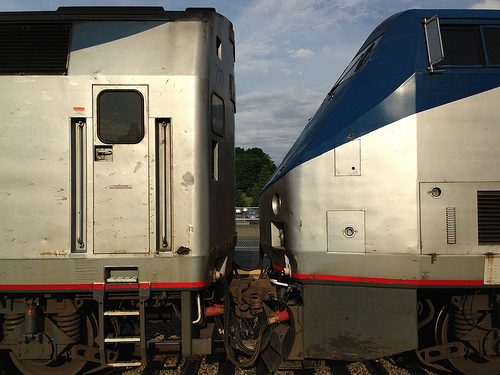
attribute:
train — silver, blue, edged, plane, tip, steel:
[2, 5, 497, 375]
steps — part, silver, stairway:
[93, 283, 151, 371]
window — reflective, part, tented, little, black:
[96, 89, 145, 144]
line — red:
[2, 282, 213, 293]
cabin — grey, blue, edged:
[258, 9, 497, 288]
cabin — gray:
[0, 5, 239, 294]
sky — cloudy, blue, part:
[1, 2, 499, 168]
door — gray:
[92, 82, 156, 256]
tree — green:
[230, 146, 277, 207]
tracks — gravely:
[1, 350, 499, 374]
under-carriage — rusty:
[2, 295, 499, 367]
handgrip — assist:
[155, 117, 174, 254]